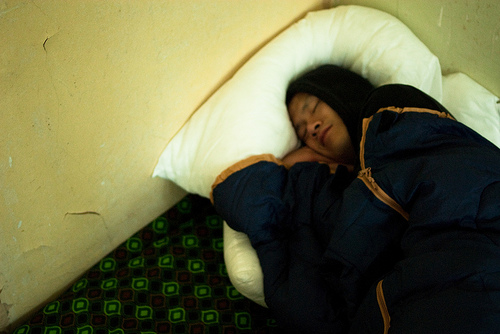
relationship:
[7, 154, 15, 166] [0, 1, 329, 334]
stain on wall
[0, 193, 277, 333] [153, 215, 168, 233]
carpet has pattern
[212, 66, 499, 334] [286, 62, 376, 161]
woman has head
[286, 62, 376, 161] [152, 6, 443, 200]
head on pillow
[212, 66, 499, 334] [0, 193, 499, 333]
woman on floor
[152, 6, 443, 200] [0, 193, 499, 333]
pillow on floor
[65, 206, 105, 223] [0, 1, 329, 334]
hole in wall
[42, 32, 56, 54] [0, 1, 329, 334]
hole in wall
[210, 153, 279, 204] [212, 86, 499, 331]
strip on coat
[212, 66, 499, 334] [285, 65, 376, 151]
woman has hair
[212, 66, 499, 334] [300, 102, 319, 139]
woman has eyes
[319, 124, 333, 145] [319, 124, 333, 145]
lipstick on lipstick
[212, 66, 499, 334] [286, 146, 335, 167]
woman has hand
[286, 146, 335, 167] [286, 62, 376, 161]
hand under head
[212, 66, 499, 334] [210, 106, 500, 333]
woman in bag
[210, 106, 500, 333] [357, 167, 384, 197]
bag with zipper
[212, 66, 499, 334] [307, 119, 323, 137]
woman has nose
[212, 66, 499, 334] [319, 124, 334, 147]
woman has mouth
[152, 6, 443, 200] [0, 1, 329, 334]
pillow beside wall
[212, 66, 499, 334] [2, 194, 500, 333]
woman on ground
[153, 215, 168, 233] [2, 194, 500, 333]
pattern on ground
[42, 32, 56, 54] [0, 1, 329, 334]
hole on wall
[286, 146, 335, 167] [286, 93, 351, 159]
hand beside face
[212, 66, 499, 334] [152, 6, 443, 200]
woman with pillow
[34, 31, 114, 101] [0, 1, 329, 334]
paint on wall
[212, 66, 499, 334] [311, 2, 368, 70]
woman in corner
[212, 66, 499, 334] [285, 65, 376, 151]
woman with hair